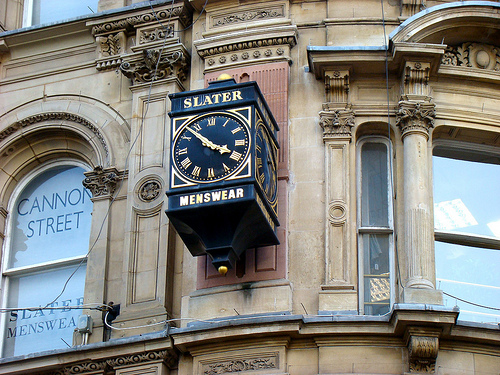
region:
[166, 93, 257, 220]
clock fixed in the wall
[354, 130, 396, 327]
window of the building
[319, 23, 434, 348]
building with some design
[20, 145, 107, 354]
some text written in the window wall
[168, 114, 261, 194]
roman letter clock with two needles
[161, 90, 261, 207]
blue color roman letter clock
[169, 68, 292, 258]
brandname written in the roman letter clock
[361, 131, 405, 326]
window made with glass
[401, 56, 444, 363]
pillar design in the building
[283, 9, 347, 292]
brown color coated building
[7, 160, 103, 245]
Cannon Street Stamped on a window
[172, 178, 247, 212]
menswear written on the bottom of a clock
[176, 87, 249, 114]
slater written on the top of the clock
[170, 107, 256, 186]
Face of the clock written in roman numberials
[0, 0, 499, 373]
Slater menswear building on cannon street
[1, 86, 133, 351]
Arches over the windows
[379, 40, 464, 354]
Pillars holding up the foundation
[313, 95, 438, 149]
Fancy carvings on the pillars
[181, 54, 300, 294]
Rust colored panel behind the clock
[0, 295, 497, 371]
Wires running along the building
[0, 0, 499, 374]
the exterior of a building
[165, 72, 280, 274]
a black and gold clock on the building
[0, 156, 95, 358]
an arched window on the building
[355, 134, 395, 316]
a narrow window on the building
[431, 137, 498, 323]
a window on the building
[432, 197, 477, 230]
fluorescent lights in the building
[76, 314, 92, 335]
an electrical box on the building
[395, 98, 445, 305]
a column on the building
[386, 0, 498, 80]
a decorative arch on the building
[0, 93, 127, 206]
a decorative arch on the building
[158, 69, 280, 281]
a clock on a building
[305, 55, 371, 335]
a stone column on a building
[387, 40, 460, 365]
a column on a building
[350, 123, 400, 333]
a window on a building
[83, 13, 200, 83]
ornate adornments on a building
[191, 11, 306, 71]
ornate adornments on a building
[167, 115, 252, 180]
numbers on a clock face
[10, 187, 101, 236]
a poster with the name of a street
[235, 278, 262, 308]
a black mark on a building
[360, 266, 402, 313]
a basket in a window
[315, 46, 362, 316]
an ornate pillar on a building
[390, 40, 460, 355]
an ornate pillar on a building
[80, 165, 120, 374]
an ornate pillar on a building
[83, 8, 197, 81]
ornate decorations on a building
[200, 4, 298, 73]
ornate decorations on a building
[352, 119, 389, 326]
the window of a building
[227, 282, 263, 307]
a dark spot of a building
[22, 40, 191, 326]
a wire coming off of a building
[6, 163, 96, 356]
the window of a building